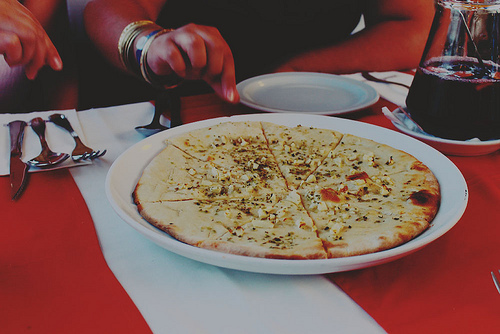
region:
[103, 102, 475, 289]
a plate of food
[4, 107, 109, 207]
the eating utensils are silver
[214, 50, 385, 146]
the plate is white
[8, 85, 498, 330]
the table is red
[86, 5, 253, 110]
the person is wearing several bracelets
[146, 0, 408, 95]
the person is wearing a dark colored shirt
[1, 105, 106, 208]
the silverware is on a napkin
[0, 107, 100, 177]
the napkin is white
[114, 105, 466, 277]
the food looks delicious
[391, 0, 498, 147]
a drink pitcher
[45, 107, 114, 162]
a metal fork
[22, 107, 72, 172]
a metal spoon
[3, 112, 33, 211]
a metal knife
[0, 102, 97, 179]
a white napkin on the table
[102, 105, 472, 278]
a white plate on the table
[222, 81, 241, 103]
the fingernail of the woman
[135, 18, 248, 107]
the hand of the woman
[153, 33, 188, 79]
the finger of the woman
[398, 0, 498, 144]
a glass pitcher filled with liquid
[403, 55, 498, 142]
purple liquid in the pitcher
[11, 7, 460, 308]
flat bread at restaurant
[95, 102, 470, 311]
plate of flatbread pizza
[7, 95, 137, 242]
place setting at restaurant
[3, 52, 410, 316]
restaurant table setting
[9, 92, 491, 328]
red place mats on restaurant table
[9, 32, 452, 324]
white pizza at italian restaurant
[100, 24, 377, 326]
woman reaching for slice of pizza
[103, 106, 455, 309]
thin crust pizza served on white plate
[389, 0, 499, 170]
glass pitcher of sangria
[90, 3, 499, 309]
italian food and wine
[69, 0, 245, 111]
colorful bracelets on an arm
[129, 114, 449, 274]
a large cheese pizza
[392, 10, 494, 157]
a glass of red wine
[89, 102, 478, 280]
fresh pizza on a white plate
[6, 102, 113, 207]
silverware on a table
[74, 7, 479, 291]
a person reaching for pizza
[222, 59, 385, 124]
a white dinner plate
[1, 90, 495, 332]
a red and white tablecloth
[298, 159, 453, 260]
a slice of cheese pizza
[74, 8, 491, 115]
a person reaching for something at a table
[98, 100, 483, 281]
Pizza in a plate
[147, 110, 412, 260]
Garlic toppings on pizza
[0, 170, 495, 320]
Red and white strips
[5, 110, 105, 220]
Spoon, knife, fork on table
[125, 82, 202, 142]
Spoon and knife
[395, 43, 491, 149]
Wine is a vase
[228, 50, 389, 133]
Smaller plate on table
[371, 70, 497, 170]
Vase is on plate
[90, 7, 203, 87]
Multicolored set of bracelets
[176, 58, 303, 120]
Short fingernails on lady